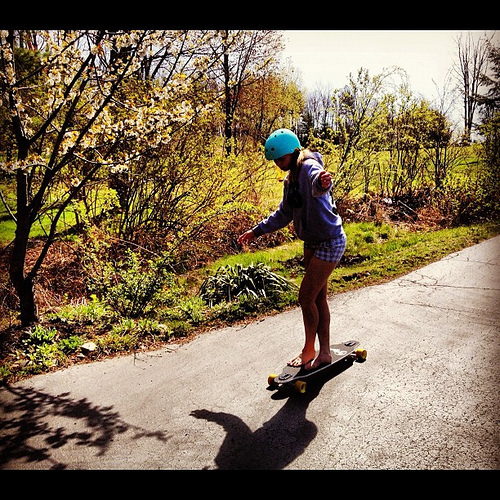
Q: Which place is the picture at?
A: It is at the sidewalk.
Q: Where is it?
A: This is at the sidewalk.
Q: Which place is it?
A: It is a sidewalk.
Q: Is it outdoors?
A: Yes, it is outdoors.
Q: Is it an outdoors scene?
A: Yes, it is outdoors.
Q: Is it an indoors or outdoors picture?
A: It is outdoors.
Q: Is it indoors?
A: No, it is outdoors.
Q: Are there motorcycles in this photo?
A: No, there are no motorcycles.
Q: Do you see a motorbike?
A: No, there are no motorcycles.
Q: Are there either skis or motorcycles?
A: No, there are no motorcycles or skis.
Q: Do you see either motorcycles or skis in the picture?
A: No, there are no motorcycles or skis.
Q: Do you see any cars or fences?
A: No, there are no fences or cars.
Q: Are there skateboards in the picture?
A: Yes, there is a skateboard.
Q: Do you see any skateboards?
A: Yes, there is a skateboard.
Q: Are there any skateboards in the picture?
A: Yes, there is a skateboard.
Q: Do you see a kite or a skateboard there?
A: Yes, there is a skateboard.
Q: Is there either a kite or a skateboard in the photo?
A: Yes, there is a skateboard.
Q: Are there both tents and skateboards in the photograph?
A: No, there is a skateboard but no tents.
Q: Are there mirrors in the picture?
A: No, there are no mirrors.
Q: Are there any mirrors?
A: No, there are no mirrors.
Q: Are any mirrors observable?
A: No, there are no mirrors.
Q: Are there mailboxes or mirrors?
A: No, there are no mirrors or mailboxes.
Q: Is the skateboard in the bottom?
A: Yes, the skateboard is in the bottom of the image.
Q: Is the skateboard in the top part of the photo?
A: No, the skateboard is in the bottom of the image.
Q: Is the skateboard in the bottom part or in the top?
A: The skateboard is in the bottom of the image.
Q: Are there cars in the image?
A: No, there are no cars.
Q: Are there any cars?
A: No, there are no cars.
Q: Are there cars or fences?
A: No, there are no cars or fences.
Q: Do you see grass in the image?
A: Yes, there is grass.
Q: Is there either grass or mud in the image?
A: Yes, there is grass.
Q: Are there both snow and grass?
A: No, there is grass but no snow.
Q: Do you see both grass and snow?
A: No, there is grass but no snow.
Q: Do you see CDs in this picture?
A: No, there are no cds.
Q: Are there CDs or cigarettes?
A: No, there are no CDs or cigarettes.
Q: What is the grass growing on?
A: The grass is growing on the field.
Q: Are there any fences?
A: No, there are no fences.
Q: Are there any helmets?
A: Yes, there is a helmet.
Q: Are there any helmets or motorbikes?
A: Yes, there is a helmet.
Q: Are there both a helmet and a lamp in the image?
A: No, there is a helmet but no lamps.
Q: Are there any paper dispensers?
A: No, there are no paper dispensers.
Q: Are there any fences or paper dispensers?
A: No, there are no paper dispensers or fences.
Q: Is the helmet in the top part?
A: Yes, the helmet is in the top of the image.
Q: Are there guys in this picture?
A: No, there are no guys.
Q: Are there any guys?
A: No, there are no guys.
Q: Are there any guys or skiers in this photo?
A: No, there are no guys or skiers.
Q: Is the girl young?
A: Yes, the girl is young.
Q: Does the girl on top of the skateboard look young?
A: Yes, the girl is young.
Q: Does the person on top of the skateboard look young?
A: Yes, the girl is young.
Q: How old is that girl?
A: The girl is young.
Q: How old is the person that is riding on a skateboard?
A: The girl is young.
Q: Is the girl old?
A: No, the girl is young.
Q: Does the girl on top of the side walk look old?
A: No, the girl is young.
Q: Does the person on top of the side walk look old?
A: No, the girl is young.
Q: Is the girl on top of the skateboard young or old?
A: The girl is young.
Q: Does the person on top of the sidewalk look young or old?
A: The girl is young.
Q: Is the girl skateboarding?
A: Yes, the girl is skateboarding.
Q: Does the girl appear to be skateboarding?
A: Yes, the girl is skateboarding.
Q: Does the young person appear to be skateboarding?
A: Yes, the girl is skateboarding.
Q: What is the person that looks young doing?
A: The girl is skateboarding.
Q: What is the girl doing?
A: The girl is skateboarding.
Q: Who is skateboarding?
A: The girl is skateboarding.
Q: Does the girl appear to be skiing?
A: No, the girl is skateboarding.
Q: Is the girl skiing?
A: No, the girl is skateboarding.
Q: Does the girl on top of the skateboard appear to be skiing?
A: No, the girl is skateboarding.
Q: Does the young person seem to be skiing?
A: No, the girl is skateboarding.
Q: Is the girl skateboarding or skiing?
A: The girl is skateboarding.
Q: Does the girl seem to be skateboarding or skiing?
A: The girl is skateboarding.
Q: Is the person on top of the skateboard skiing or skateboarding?
A: The girl is skateboarding.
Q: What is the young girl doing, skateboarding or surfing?
A: The girl is skateboarding.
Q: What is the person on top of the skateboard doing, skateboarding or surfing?
A: The girl is skateboarding.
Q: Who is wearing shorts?
A: The girl is wearing shorts.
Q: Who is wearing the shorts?
A: The girl is wearing shorts.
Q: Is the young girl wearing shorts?
A: Yes, the girl is wearing shorts.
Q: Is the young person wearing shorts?
A: Yes, the girl is wearing shorts.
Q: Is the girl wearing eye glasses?
A: No, the girl is wearing shorts.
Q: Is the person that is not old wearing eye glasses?
A: No, the girl is wearing shorts.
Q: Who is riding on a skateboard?
A: The girl is riding on a skateboard.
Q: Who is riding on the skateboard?
A: The girl is riding on a skateboard.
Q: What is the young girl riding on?
A: The girl is riding on a skateboard.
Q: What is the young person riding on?
A: The girl is riding on a skateboard.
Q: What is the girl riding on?
A: The girl is riding on a skateboard.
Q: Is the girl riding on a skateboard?
A: Yes, the girl is riding on a skateboard.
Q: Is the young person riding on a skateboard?
A: Yes, the girl is riding on a skateboard.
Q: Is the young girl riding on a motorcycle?
A: No, the girl is riding on a skateboard.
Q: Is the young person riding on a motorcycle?
A: No, the girl is riding on a skateboard.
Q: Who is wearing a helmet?
A: The girl is wearing a helmet.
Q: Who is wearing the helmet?
A: The girl is wearing a helmet.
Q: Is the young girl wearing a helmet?
A: Yes, the girl is wearing a helmet.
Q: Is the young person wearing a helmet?
A: Yes, the girl is wearing a helmet.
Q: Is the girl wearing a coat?
A: No, the girl is wearing a helmet.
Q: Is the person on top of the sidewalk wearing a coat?
A: No, the girl is wearing a helmet.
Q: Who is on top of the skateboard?
A: The girl is on top of the skateboard.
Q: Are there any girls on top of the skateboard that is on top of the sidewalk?
A: Yes, there is a girl on top of the skateboard.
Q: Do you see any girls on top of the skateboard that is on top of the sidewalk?
A: Yes, there is a girl on top of the skateboard.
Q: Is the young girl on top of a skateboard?
A: Yes, the girl is on top of a skateboard.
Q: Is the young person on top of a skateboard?
A: Yes, the girl is on top of a skateboard.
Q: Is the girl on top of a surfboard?
A: No, the girl is on top of a skateboard.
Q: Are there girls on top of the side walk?
A: Yes, there is a girl on top of the side walk.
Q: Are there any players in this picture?
A: No, there are no players.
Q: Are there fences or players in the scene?
A: No, there are no players or fences.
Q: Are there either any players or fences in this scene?
A: No, there are no players or fences.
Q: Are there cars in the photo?
A: No, there are no cars.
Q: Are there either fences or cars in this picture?
A: No, there are no cars or fences.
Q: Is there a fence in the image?
A: No, there are no fences.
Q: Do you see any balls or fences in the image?
A: No, there are no fences or balls.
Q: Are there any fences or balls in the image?
A: No, there are no fences or balls.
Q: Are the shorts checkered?
A: Yes, the shorts are checkered.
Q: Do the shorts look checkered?
A: Yes, the shorts are checkered.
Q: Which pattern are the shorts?
A: The shorts are checkered.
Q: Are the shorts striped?
A: No, the shorts are checkered.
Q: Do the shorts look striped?
A: No, the shorts are checkered.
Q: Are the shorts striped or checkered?
A: The shorts are checkered.